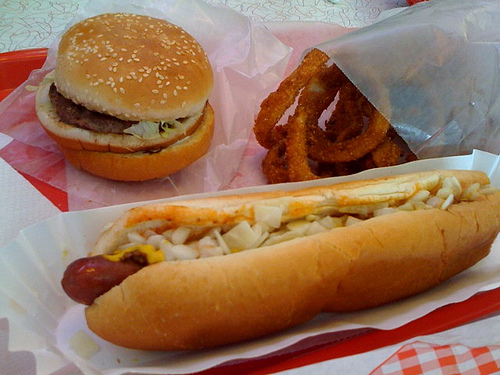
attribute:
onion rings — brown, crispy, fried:
[253, 49, 419, 186]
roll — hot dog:
[74, 147, 174, 178]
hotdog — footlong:
[34, 187, 491, 333]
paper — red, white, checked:
[368, 340, 498, 374]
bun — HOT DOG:
[85, 167, 498, 353]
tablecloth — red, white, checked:
[399, 329, 464, 359]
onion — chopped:
[224, 222, 256, 247]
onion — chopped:
[169, 224, 191, 243]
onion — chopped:
[252, 204, 284, 227]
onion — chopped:
[301, 218, 323, 236]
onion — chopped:
[434, 188, 452, 200]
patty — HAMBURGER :
[39, 95, 154, 178]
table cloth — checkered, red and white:
[376, 341, 498, 373]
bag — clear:
[321, 30, 490, 163]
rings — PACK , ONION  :
[245, 57, 482, 162]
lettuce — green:
[119, 114, 169, 149]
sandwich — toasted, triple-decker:
[40, 10, 217, 185]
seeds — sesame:
[97, 43, 140, 73]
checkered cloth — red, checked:
[368, 338, 498, 373]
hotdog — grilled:
[69, 157, 496, 357]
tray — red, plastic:
[0, 2, 498, 374]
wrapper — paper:
[2, 0, 499, 215]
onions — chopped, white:
[125, 178, 495, 260]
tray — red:
[17, 13, 418, 373]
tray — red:
[4, 42, 89, 177]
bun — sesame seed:
[51, 12, 206, 118]